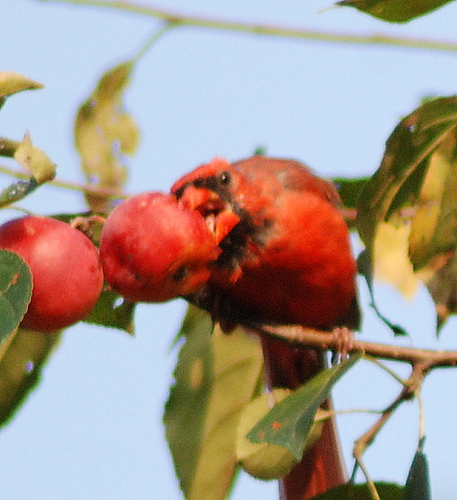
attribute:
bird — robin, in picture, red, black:
[170, 158, 360, 500]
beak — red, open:
[181, 189, 240, 245]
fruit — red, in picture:
[101, 193, 218, 304]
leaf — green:
[0, 250, 33, 360]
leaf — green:
[50, 215, 137, 338]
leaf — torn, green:
[246, 351, 364, 463]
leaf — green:
[338, 1, 451, 24]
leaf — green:
[356, 95, 456, 340]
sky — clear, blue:
[0, 1, 456, 498]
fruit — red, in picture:
[0, 214, 103, 332]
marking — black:
[174, 176, 253, 261]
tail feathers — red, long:
[263, 333, 347, 499]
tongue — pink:
[205, 213, 217, 231]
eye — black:
[220, 172, 229, 185]